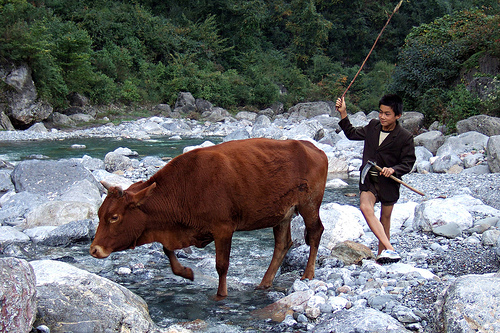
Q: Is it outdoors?
A: Yes, it is outdoors.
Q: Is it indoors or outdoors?
A: It is outdoors.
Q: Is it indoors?
A: No, it is outdoors.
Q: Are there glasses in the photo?
A: No, there are no glasses.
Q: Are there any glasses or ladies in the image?
A: No, there are no glasses or ladies.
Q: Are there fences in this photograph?
A: No, there are no fences.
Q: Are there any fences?
A: No, there are no fences.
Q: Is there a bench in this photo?
A: No, there are no benches.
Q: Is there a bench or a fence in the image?
A: No, there are no benches or fences.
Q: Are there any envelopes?
A: No, there are no envelopes.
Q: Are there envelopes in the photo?
A: No, there are no envelopes.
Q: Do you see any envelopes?
A: No, there are no envelopes.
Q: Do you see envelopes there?
A: No, there are no envelopes.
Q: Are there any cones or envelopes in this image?
A: No, there are no envelopes or cones.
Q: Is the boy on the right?
A: Yes, the boy is on the right of the image.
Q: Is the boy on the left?
A: No, the boy is on the right of the image.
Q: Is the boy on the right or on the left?
A: The boy is on the right of the image.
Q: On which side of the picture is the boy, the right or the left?
A: The boy is on the right of the image.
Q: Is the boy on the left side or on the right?
A: The boy is on the right of the image.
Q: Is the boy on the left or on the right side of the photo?
A: The boy is on the right of the image.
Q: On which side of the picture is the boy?
A: The boy is on the right of the image.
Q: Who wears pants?
A: The boy wears pants.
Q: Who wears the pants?
A: The boy wears pants.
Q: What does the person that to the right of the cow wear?
A: The boy wears trousers.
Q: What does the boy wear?
A: The boy wears trousers.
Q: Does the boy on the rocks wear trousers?
A: Yes, the boy wears trousers.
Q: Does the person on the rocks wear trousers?
A: Yes, the boy wears trousers.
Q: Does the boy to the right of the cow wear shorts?
A: No, the boy wears trousers.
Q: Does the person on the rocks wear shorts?
A: No, the boy wears trousers.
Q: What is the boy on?
A: The boy is on the rocks.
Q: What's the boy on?
A: The boy is on the rocks.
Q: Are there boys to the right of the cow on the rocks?
A: Yes, there is a boy to the right of the cow.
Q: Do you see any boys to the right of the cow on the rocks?
A: Yes, there is a boy to the right of the cow.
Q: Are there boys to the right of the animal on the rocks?
A: Yes, there is a boy to the right of the cow.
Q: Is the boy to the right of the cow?
A: Yes, the boy is to the right of the cow.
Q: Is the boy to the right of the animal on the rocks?
A: Yes, the boy is to the right of the cow.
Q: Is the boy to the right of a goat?
A: No, the boy is to the right of the cow.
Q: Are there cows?
A: Yes, there is a cow.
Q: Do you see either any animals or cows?
A: Yes, there is a cow.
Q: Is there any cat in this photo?
A: No, there are no cats.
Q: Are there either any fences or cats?
A: No, there are no cats or fences.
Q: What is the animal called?
A: The animal is a cow.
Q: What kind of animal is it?
A: The animal is a cow.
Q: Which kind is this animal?
A: That is a cow.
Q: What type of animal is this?
A: That is a cow.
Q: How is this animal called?
A: That is a cow.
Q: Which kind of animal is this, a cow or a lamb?
A: That is a cow.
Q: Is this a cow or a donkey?
A: This is a cow.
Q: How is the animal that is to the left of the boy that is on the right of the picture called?
A: The animal is a cow.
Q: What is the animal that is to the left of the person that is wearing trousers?
A: The animal is a cow.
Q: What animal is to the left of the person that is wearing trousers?
A: The animal is a cow.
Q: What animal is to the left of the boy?
A: The animal is a cow.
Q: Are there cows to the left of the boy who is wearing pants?
A: Yes, there is a cow to the left of the boy.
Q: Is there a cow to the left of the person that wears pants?
A: Yes, there is a cow to the left of the boy.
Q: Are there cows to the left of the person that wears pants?
A: Yes, there is a cow to the left of the boy.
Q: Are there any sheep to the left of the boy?
A: No, there is a cow to the left of the boy.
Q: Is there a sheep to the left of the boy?
A: No, there is a cow to the left of the boy.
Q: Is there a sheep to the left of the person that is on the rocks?
A: No, there is a cow to the left of the boy.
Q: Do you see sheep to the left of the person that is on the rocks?
A: No, there is a cow to the left of the boy.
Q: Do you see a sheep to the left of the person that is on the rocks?
A: No, there is a cow to the left of the boy.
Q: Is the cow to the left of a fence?
A: No, the cow is to the left of the boy.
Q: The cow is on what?
A: The cow is on the rocks.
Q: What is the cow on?
A: The cow is on the rocks.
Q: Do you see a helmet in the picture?
A: No, there are no helmets.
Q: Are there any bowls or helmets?
A: No, there are no helmets or bowls.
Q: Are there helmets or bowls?
A: No, there are no helmets or bowls.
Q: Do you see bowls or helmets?
A: No, there are no helmets or bowls.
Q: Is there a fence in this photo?
A: No, there are no fences.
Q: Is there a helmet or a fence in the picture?
A: No, there are no fences or helmets.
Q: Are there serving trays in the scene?
A: No, there are no serving trays.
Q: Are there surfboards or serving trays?
A: No, there are no serving trays or surfboards.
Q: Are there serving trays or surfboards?
A: No, there are no serving trays or surfboards.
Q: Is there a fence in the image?
A: No, there are no fences.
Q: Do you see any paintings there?
A: No, there are no paintings.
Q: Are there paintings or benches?
A: No, there are no paintings or benches.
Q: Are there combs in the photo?
A: No, there are no combs.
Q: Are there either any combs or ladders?
A: No, there are no combs or ladders.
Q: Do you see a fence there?
A: No, there are no fences.